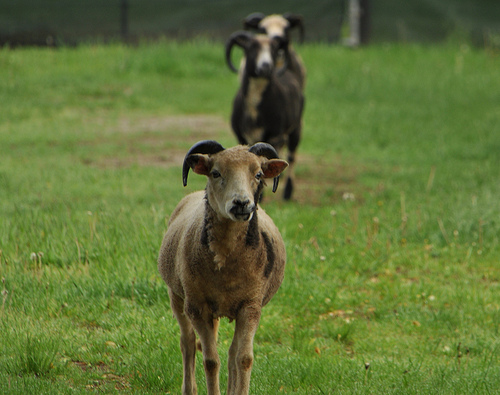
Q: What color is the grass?
A: Green.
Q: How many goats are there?
A: 2.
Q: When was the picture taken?
A: In the daytime.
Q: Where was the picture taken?
A: In a field.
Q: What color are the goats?
A: Brown.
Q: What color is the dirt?
A: Light brown.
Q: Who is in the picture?
A: 2 goats.